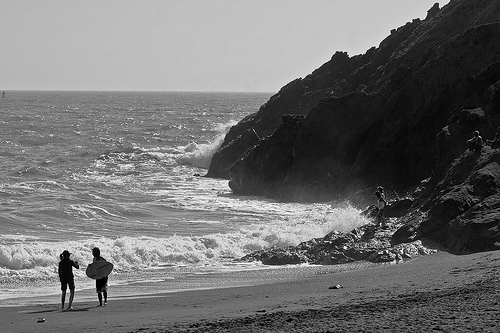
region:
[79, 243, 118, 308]
The person is holding on to the surfboard.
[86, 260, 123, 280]
The surfboard is white.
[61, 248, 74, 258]
The woman is wearing a hat.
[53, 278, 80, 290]
The woman is wearing a short pant.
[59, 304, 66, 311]
The left foot of the woman.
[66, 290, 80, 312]
The right foot of the woman.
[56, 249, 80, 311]
woman standing on the beach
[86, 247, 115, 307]
man standing on the beach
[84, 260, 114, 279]
man holding a surf board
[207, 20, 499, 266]
ocean crashing into rocks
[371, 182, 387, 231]
man standing on the rocks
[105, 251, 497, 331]
tracks in the sand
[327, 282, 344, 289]
trash on the sand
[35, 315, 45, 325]
trash on the sand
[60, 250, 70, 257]
woman wear a cap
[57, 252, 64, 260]
woman wearing a ponytail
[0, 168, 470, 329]
this is a beach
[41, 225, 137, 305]
people on a beach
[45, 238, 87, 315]
this is a person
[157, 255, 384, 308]
sand on the beach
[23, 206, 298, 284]
waves of the water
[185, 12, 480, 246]
rocks next to water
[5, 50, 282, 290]
a large body of water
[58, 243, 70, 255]
The woman is wearing a hat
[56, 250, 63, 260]
The ponytail of the woman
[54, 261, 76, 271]
The woman is wearing a shirt.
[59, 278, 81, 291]
The woman is wearing a short pant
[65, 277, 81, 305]
The right foot of the woman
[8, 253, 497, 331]
The beach is sandy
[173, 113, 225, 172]
The waves are crashing on the rocks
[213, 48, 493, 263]
The rocks are black.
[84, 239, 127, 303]
The person is holding a surfboard.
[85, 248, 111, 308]
Person holding a surfboard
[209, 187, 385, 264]
Waves crashing the rocks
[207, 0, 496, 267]
Rocks alongside the water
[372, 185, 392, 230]
Person standing on the rocks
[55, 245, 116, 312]
Two people walking and talking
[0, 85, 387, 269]
Water in a large body of water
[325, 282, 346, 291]
Trash laying on the beach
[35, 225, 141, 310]
people next to water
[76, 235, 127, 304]
person with a board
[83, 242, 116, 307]
man on beach holding surfboard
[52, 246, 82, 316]
woman with pony tail on beach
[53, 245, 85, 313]
woman standing on sandy beach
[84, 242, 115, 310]
man standing on sandy beach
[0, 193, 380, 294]
waves breaking on shore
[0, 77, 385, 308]
body of water beyond beach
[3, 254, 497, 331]
sandy beach near water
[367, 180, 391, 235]
person standing on rocky shore